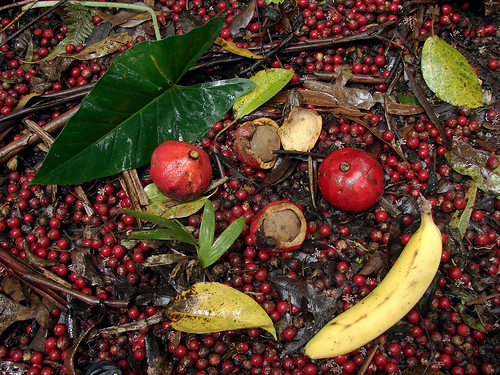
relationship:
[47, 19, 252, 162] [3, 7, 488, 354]
leaf on ground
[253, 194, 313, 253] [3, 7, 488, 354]
nut on ground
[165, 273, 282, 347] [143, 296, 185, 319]
leaf with stem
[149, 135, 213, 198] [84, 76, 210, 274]
pomegranate on leaves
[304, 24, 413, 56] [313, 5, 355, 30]
twigs on cranberries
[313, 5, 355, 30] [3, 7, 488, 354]
cranberries on ground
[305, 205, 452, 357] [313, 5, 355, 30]
banana on cranberries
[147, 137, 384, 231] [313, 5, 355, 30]
pomegranates laying on cranberries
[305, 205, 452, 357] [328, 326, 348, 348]
banana with peel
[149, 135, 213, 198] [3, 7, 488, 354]
pomegranate on ground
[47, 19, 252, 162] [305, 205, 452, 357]
leaf near banana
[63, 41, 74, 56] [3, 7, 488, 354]
cranberry on ground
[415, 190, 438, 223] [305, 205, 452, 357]
stem of banana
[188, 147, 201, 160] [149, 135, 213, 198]
stem on pomegranate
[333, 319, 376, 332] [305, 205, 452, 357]
marks on banana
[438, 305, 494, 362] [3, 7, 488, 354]
coffee on ground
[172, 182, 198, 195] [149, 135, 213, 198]
skin on fruit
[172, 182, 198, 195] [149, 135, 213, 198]
skin of fruit